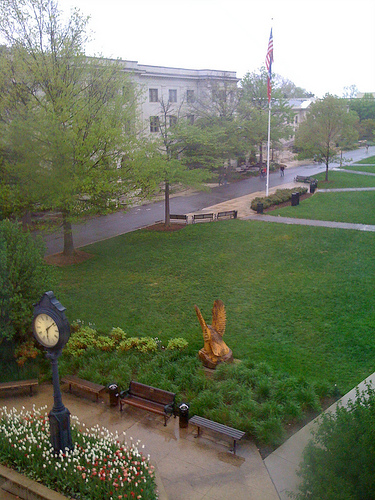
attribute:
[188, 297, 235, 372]
statue — eagle , brown 